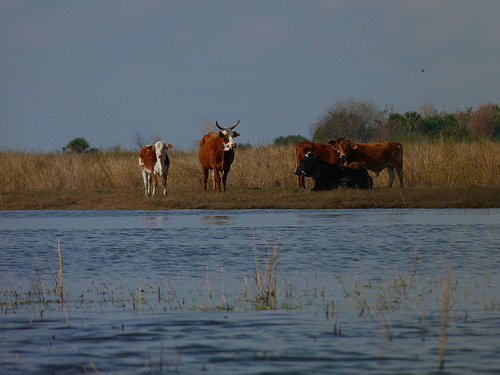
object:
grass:
[11, 148, 132, 197]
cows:
[122, 112, 411, 196]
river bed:
[38, 175, 482, 206]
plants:
[130, 243, 465, 318]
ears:
[226, 125, 247, 138]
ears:
[142, 141, 182, 151]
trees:
[296, 93, 493, 149]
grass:
[13, 134, 498, 197]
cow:
[137, 134, 196, 194]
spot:
[218, 128, 228, 142]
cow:
[198, 120, 240, 189]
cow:
[330, 131, 409, 199]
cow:
[279, 138, 339, 188]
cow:
[318, 165, 378, 193]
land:
[7, 141, 499, 203]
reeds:
[267, 130, 470, 184]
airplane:
[328, 65, 386, 72]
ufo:
[364, 304, 406, 326]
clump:
[314, 128, 436, 178]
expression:
[195, 119, 253, 168]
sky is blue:
[2, 1, 494, 126]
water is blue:
[4, 207, 500, 372]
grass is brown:
[0, 151, 138, 193]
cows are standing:
[137, 119, 411, 200]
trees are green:
[392, 100, 467, 145]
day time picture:
[2, 5, 493, 365]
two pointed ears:
[139, 138, 181, 153]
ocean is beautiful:
[4, 204, 500, 373]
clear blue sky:
[2, 4, 486, 144]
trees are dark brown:
[323, 88, 396, 141]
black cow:
[296, 147, 375, 188]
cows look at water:
[135, 117, 240, 195]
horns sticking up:
[215, 117, 243, 131]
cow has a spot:
[196, 115, 250, 194]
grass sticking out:
[4, 223, 495, 342]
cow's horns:
[214, 117, 244, 130]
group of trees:
[269, 93, 496, 183]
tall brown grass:
[402, 124, 500, 193]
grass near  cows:
[239, 140, 298, 186]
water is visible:
[2, 202, 499, 371]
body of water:
[6, 210, 500, 367]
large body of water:
[4, 205, 499, 373]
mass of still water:
[6, 208, 492, 370]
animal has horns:
[193, 116, 244, 196]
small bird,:
[417, 61, 429, 76]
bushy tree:
[63, 135, 95, 154]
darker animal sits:
[295, 150, 376, 191]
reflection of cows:
[141, 204, 415, 237]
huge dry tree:
[304, 97, 395, 138]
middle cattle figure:
[196, 118, 246, 193]